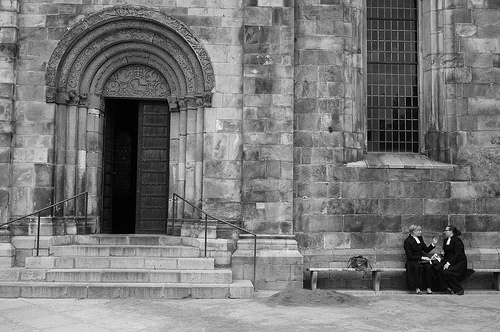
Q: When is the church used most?
A: Sundays.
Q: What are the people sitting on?
A: Bench.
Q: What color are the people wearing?
A: Black.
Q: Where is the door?
A: Top of the stairs.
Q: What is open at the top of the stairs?
A: Door.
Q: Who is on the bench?
A: People.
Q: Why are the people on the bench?
A: To sit and talk.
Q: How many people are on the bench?
A: Two.